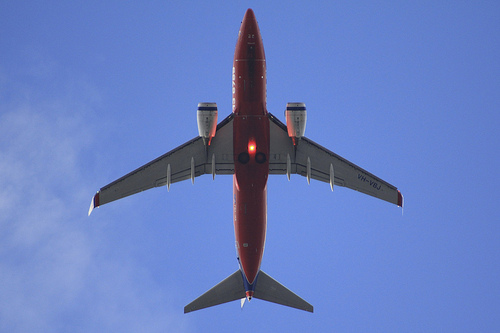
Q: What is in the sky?
A: A plane.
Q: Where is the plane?
A: In the sky.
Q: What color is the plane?
A: Red.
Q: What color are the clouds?
A: White.